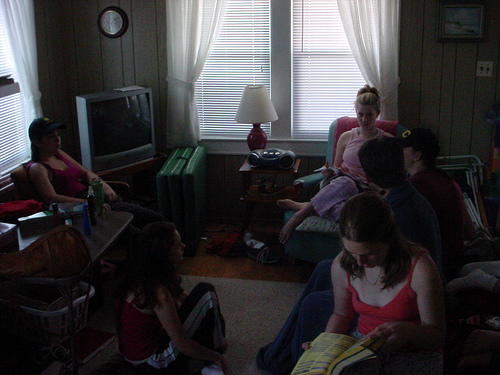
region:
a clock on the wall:
[98, 9, 127, 36]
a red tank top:
[340, 254, 427, 341]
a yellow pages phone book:
[292, 332, 389, 373]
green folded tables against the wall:
[154, 146, 208, 245]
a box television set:
[74, 85, 163, 165]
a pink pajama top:
[342, 129, 384, 184]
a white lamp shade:
[236, 82, 276, 124]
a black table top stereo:
[248, 147, 295, 170]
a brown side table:
[235, 152, 297, 257]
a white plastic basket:
[16, 283, 92, 347]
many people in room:
[5, 44, 487, 332]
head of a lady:
[307, 195, 424, 298]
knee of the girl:
[181, 262, 237, 328]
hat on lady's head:
[26, 111, 68, 143]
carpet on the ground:
[215, 267, 288, 345]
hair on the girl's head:
[116, 225, 176, 291]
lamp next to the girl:
[218, 71, 295, 149]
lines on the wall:
[388, 62, 475, 109]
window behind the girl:
[293, 5, 371, 76]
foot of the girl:
[268, 207, 306, 254]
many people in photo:
[6, 64, 471, 341]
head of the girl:
[301, 186, 426, 306]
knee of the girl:
[160, 273, 231, 338]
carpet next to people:
[221, 255, 289, 325]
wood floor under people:
[206, 248, 260, 280]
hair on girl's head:
[117, 222, 179, 299]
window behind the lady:
[278, 14, 379, 90]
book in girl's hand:
[298, 324, 400, 374]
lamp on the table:
[211, 72, 295, 157]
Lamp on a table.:
[230, 83, 280, 152]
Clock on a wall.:
[92, 3, 132, 38]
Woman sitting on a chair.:
[26, 117, 151, 232]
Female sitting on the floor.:
[116, 217, 241, 369]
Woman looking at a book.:
[290, 194, 447, 373]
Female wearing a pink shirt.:
[283, 88, 397, 237]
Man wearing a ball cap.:
[396, 123, 483, 246]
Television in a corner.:
[61, 80, 158, 180]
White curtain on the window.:
[165, 2, 223, 144]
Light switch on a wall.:
[470, 55, 497, 80]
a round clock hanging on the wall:
[96, 5, 126, 35]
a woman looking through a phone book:
[280, 194, 446, 374]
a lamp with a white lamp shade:
[237, 82, 280, 152]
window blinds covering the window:
[196, 1, 368, 136]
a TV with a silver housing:
[58, 83, 154, 176]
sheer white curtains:
[163, 0, 402, 153]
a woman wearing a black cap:
[28, 108, 153, 241]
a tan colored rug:
[79, 271, 305, 372]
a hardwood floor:
[176, 220, 318, 282]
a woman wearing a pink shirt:
[273, 83, 398, 246]